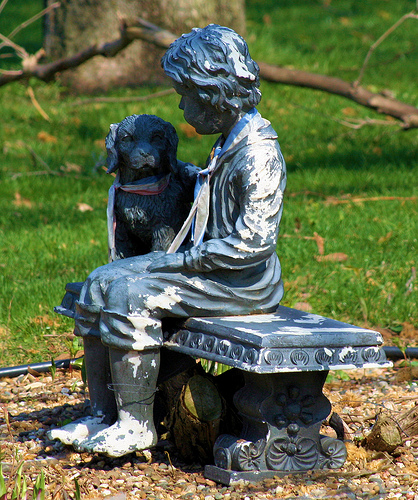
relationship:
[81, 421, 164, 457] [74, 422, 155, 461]
paint on foot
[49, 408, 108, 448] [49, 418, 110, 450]
paint on foot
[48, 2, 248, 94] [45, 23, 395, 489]
tree behind statue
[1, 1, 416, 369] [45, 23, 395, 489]
grass around statue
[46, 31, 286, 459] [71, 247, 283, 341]
boy has pants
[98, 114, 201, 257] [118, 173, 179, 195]
dog has collar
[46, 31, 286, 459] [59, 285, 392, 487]
boy sitting on bench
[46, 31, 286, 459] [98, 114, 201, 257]
boy looking at dog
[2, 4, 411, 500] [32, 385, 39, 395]
ground has stone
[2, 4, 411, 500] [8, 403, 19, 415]
ground has stone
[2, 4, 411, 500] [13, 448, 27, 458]
ground has stone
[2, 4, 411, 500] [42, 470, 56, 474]
ground has stone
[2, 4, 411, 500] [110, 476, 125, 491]
ground has stone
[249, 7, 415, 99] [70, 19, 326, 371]
area behind statue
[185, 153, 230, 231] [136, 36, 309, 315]
ribbons around statue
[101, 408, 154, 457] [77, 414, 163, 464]
patches on foot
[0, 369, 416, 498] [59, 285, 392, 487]
rocks surround bench